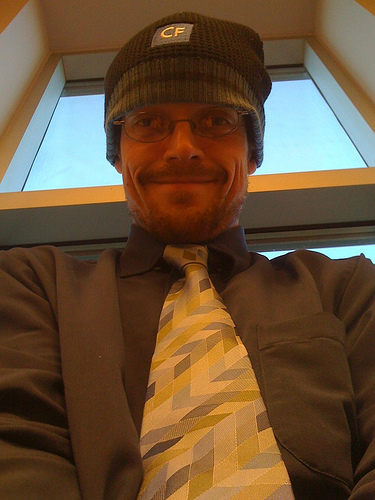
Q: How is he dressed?
A: In a suit.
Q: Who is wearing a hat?
A: Man.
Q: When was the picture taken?
A: Daytime.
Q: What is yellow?
A: Tie.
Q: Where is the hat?
A: On his head.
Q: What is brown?
A: Jacket.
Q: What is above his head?
A: Window.